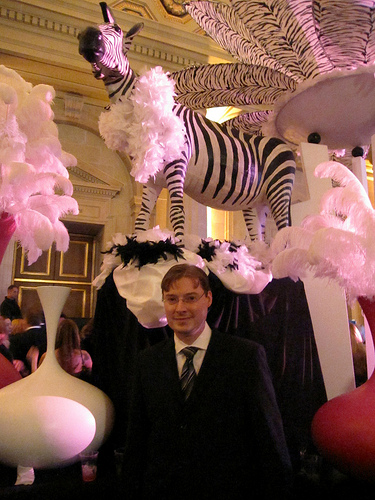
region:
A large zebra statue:
[73, 1, 307, 243]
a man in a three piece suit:
[117, 264, 278, 498]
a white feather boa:
[99, 68, 188, 176]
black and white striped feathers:
[171, 65, 295, 101]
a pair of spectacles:
[156, 289, 211, 304]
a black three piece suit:
[131, 324, 274, 498]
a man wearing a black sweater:
[2, 283, 24, 318]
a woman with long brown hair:
[56, 323, 98, 378]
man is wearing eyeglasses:
[153, 283, 254, 344]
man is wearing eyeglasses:
[146, 278, 211, 321]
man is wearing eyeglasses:
[157, 292, 213, 309]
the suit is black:
[125, 295, 240, 486]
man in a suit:
[111, 263, 300, 489]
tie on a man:
[166, 344, 201, 402]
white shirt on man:
[168, 332, 212, 399]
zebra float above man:
[76, 2, 296, 231]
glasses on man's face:
[152, 291, 210, 304]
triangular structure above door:
[18, 149, 120, 197]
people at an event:
[0, 283, 93, 373]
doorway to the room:
[14, 241, 94, 318]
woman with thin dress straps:
[30, 316, 96, 371]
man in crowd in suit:
[12, 311, 50, 351]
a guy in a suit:
[116, 263, 296, 499]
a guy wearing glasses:
[159, 285, 209, 305]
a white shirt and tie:
[171, 325, 211, 398]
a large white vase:
[4, 282, 113, 467]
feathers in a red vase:
[271, 159, 374, 478]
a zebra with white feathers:
[77, 4, 307, 258]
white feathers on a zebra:
[71, 0, 306, 245]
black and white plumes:
[170, 4, 373, 95]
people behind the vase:
[0, 271, 98, 399]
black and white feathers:
[101, 229, 194, 262]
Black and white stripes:
[171, 212, 185, 237]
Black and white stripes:
[165, 184, 175, 192]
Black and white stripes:
[132, 176, 163, 201]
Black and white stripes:
[133, 193, 168, 222]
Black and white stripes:
[126, 207, 158, 227]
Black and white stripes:
[178, 132, 216, 163]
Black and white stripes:
[195, 159, 240, 194]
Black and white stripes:
[231, 134, 273, 161]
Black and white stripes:
[253, 150, 271, 169]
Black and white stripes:
[266, 171, 302, 206]